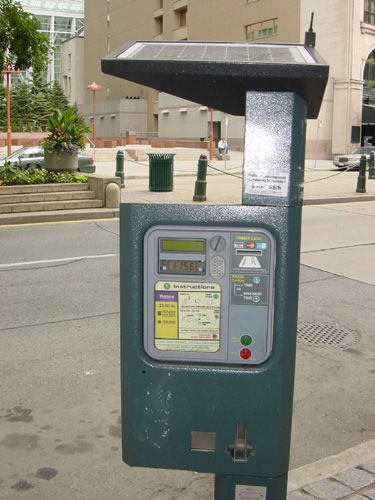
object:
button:
[239, 333, 252, 347]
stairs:
[0, 183, 121, 225]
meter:
[97, 40, 333, 500]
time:
[164, 261, 198, 272]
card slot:
[236, 249, 261, 258]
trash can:
[146, 153, 176, 195]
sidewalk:
[70, 161, 374, 204]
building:
[84, 0, 374, 159]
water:
[0, 424, 41, 451]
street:
[3, 193, 375, 443]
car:
[0, 144, 100, 177]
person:
[217, 137, 229, 155]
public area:
[74, 140, 244, 183]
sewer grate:
[295, 322, 360, 351]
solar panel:
[115, 46, 311, 68]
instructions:
[153, 281, 218, 354]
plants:
[37, 103, 94, 165]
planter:
[44, 146, 80, 172]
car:
[334, 146, 374, 170]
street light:
[89, 82, 101, 148]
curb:
[0, 206, 119, 226]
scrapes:
[142, 370, 179, 455]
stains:
[345, 349, 373, 378]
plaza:
[3, 133, 375, 216]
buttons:
[238, 348, 253, 361]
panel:
[145, 224, 275, 369]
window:
[158, 257, 207, 278]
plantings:
[0, 158, 89, 185]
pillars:
[114, 150, 126, 190]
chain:
[209, 164, 360, 182]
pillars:
[190, 155, 209, 202]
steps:
[76, 148, 228, 162]